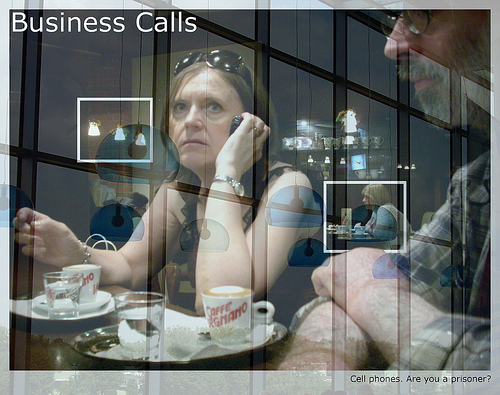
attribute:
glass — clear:
[108, 283, 177, 364]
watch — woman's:
[206, 164, 249, 207]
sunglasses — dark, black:
[166, 43, 263, 87]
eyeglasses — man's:
[369, 9, 456, 49]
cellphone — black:
[221, 112, 255, 142]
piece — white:
[128, 315, 213, 361]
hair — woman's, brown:
[156, 55, 296, 205]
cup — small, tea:
[197, 278, 276, 348]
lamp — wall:
[303, 151, 316, 164]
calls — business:
[7, 10, 217, 47]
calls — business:
[6, 8, 201, 41]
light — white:
[86, 120, 102, 138]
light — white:
[110, 123, 125, 139]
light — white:
[133, 130, 146, 146]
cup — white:
[200, 287, 273, 347]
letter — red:
[240, 300, 248, 312]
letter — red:
[232, 304, 242, 318]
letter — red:
[228, 309, 235, 321]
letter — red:
[218, 313, 228, 325]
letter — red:
[222, 300, 232, 311]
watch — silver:
[210, 173, 245, 198]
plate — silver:
[66, 315, 288, 366]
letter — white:
[10, 10, 28, 32]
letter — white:
[45, 15, 58, 32]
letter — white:
[84, 15, 98, 33]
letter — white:
[134, 10, 154, 33]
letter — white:
[184, 15, 197, 32]